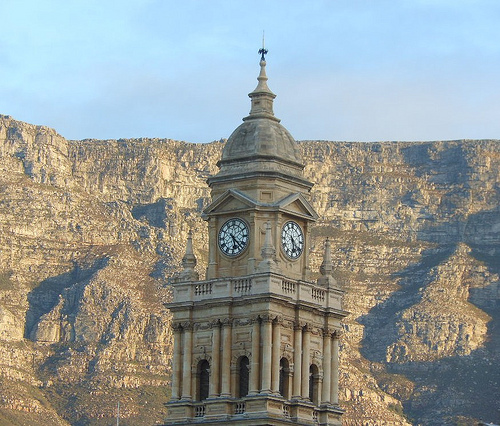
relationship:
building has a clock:
[162, 30, 348, 424] [219, 219, 248, 257]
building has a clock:
[162, 30, 348, 424] [281, 220, 303, 259]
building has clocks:
[162, 30, 348, 424] [218, 218, 304, 262]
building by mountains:
[162, 30, 348, 424] [0, 112, 499, 425]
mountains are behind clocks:
[0, 112, 499, 425] [218, 218, 304, 262]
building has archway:
[162, 30, 348, 424] [195, 356, 210, 415]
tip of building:
[259, 28, 267, 55] [162, 30, 348, 424]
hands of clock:
[228, 231, 244, 250] [219, 219, 248, 257]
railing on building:
[191, 399, 207, 420] [162, 30, 348, 424]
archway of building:
[233, 354, 249, 416] [162, 30, 348, 424]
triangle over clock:
[201, 189, 258, 217] [219, 219, 248, 257]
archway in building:
[278, 354, 291, 416] [162, 30, 348, 424]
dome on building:
[216, 118, 304, 174] [162, 30, 348, 424]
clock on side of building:
[219, 219, 248, 257] [162, 30, 348, 424]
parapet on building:
[165, 271, 343, 312] [162, 30, 348, 424]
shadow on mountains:
[356, 213, 497, 425] [0, 112, 499, 425]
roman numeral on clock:
[230, 219, 238, 227] [219, 219, 248, 257]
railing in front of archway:
[191, 399, 207, 420] [195, 356, 210, 415]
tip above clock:
[259, 28, 267, 55] [219, 219, 248, 257]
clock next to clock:
[219, 219, 248, 257] [281, 220, 303, 259]